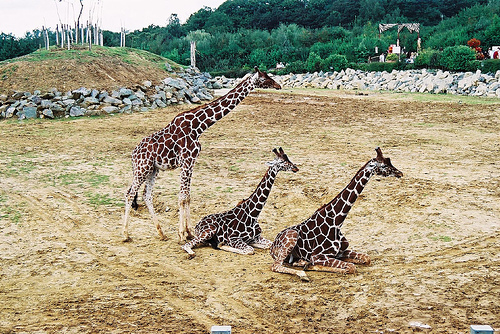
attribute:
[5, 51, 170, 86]
grassy mound — small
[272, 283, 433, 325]
dirt — loose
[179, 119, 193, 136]
spot — brown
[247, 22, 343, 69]
trees — tall, green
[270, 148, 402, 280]
giraffe — brown, white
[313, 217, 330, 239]
spot — brown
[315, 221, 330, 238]
spot — brown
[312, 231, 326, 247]
spot — brown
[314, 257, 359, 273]
leg — folded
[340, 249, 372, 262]
leg — folded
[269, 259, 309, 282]
leg — folded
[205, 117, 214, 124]
spot — brown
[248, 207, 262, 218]
spot — brown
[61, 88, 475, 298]
dirt — tan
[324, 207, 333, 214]
spot — brown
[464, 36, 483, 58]
tree — red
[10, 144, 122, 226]
grass — little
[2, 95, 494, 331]
ground — brown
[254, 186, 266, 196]
spot — brown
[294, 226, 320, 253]
spot — brown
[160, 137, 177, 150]
spot — brown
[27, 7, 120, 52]
trees — spindly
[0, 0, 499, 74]
vegetation — thick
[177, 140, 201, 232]
legs — long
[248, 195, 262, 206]
spot — brown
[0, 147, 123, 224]
grass — small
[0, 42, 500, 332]
area — animal's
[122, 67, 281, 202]
spots — brown